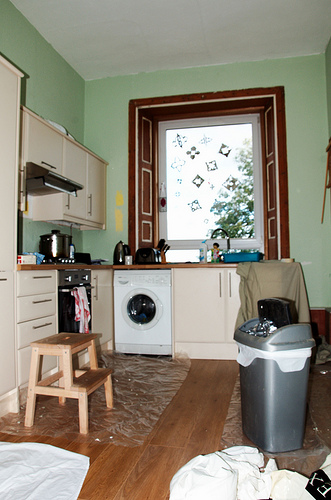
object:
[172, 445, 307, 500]
cloth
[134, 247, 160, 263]
toaster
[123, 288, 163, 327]
circular dishwaher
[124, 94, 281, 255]
window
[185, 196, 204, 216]
stickers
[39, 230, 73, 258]
pot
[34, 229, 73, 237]
lid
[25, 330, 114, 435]
wooden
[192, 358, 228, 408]
wooden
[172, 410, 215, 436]
wooden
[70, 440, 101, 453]
wooden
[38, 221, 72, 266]
cooker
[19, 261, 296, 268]
counter top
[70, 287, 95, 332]
towel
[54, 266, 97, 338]
oven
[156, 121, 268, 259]
frame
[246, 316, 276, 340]
garbage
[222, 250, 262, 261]
utility bin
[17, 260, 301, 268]
counter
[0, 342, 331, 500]
floor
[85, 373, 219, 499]
wood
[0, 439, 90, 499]
blanket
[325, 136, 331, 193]
towel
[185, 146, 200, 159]
sticker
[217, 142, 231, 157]
sticker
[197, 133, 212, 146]
sticker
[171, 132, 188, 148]
sticker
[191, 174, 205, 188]
sticker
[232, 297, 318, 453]
trash can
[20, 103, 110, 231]
cabinets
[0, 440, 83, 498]
sheet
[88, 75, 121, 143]
green wall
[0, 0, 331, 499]
kitchen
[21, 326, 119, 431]
step stool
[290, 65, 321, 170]
walls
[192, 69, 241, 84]
mint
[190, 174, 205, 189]
decals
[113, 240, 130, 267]
iron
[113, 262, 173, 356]
dishwasher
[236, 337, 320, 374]
bag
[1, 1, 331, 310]
background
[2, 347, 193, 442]
plastic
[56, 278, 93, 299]
oven handle